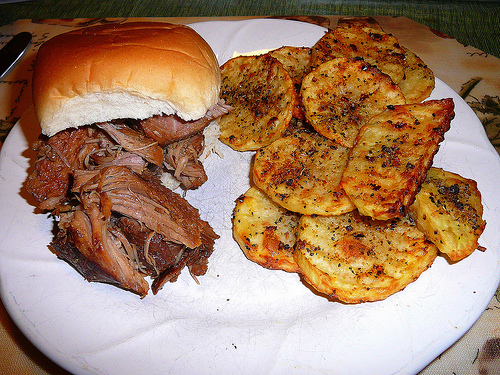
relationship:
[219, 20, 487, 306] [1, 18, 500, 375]
chips on dish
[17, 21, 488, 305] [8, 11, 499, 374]
food on a table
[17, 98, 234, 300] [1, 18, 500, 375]
grilled meat on dish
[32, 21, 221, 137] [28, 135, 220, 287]
bread on pork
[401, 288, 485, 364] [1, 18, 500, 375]
edge of dish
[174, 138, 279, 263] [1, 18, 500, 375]
cracks on dish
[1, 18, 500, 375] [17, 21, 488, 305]
dish of food